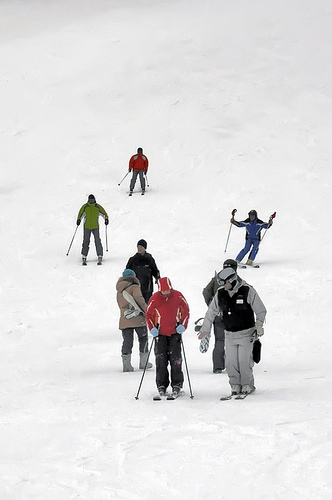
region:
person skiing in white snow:
[123, 145, 150, 195]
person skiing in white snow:
[71, 193, 109, 269]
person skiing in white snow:
[128, 241, 156, 264]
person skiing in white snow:
[116, 266, 150, 364]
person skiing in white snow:
[147, 280, 189, 404]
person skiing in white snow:
[222, 210, 269, 265]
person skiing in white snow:
[200, 273, 264, 398]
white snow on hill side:
[35, 391, 87, 444]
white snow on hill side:
[131, 433, 200, 482]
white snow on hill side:
[222, 411, 310, 471]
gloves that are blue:
[175, 324, 184, 333]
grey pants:
[224, 334, 253, 387]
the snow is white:
[56, 412, 187, 476]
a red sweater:
[151, 297, 183, 324]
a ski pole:
[132, 369, 156, 397]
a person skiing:
[229, 207, 279, 257]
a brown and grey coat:
[111, 281, 142, 331]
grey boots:
[119, 356, 134, 373]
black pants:
[156, 338, 185, 385]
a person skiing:
[72, 196, 114, 263]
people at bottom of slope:
[114, 233, 265, 401]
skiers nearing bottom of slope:
[59, 139, 275, 264]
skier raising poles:
[219, 190, 274, 266]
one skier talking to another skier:
[130, 264, 264, 400]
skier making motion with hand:
[193, 265, 265, 404]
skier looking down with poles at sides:
[132, 275, 191, 399]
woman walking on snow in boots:
[111, 265, 148, 368]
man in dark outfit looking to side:
[121, 236, 157, 296]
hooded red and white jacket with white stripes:
[143, 272, 187, 333]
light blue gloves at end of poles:
[127, 323, 193, 399]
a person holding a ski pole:
[174, 332, 203, 393]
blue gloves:
[148, 328, 160, 337]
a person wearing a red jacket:
[149, 287, 190, 329]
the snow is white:
[69, 399, 268, 494]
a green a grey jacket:
[80, 205, 101, 231]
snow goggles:
[214, 277, 226, 286]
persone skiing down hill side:
[122, 142, 159, 194]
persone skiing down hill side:
[65, 186, 113, 271]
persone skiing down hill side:
[134, 262, 198, 425]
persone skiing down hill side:
[211, 267, 267, 404]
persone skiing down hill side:
[222, 199, 269, 278]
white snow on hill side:
[19, 304, 73, 371]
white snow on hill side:
[109, 426, 182, 480]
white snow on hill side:
[204, 429, 249, 473]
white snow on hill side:
[216, 106, 310, 172]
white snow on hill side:
[143, 81, 226, 148]